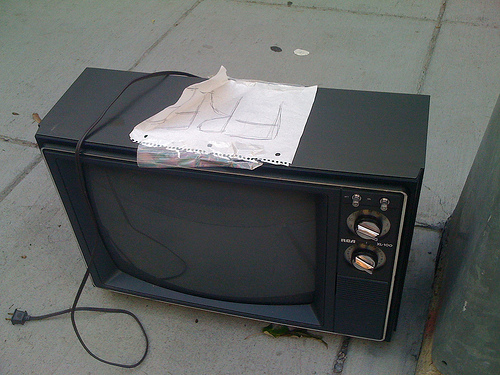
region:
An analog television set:
[40, 70, 408, 328]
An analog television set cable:
[5, 293, 156, 368]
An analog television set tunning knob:
[350, 241, 385, 274]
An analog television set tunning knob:
[348, 208, 387, 240]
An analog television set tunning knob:
[376, 196, 392, 213]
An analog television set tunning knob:
[347, 187, 362, 207]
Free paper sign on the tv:
[132, 74, 319, 167]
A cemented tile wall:
[161, 16, 445, 91]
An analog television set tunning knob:
[9, 167, 71, 279]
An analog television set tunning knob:
[1, 326, 84, 367]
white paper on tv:
[135, 74, 337, 186]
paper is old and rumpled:
[137, 66, 324, 184]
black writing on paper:
[136, 56, 266, 175]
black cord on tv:
[25, 54, 184, 374]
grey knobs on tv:
[326, 214, 379, 286]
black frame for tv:
[63, 63, 402, 355]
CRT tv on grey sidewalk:
[42, 55, 397, 352]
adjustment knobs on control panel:
[344, 191, 384, 291]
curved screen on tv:
[99, 163, 301, 330]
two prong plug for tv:
[12, 301, 38, 335]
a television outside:
[16, 58, 453, 359]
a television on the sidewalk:
[23, 54, 424, 372]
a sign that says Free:
[135, 73, 307, 174]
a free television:
[41, 63, 437, 348]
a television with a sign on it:
[21, 56, 446, 366]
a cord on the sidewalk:
[6, 298, 168, 365]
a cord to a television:
[4, 52, 155, 372]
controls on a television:
[336, 189, 395, 280]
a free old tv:
[9, 50, 436, 374]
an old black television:
[4, 53, 431, 370]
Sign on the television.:
[137, 63, 319, 171]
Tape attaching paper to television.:
[131, 134, 263, 179]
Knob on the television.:
[347, 203, 382, 285]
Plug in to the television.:
[2, 303, 43, 331]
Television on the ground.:
[27, 61, 435, 358]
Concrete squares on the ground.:
[2, 1, 495, 373]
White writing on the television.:
[337, 234, 358, 248]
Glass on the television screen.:
[64, 154, 330, 306]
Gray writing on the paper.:
[152, 83, 284, 142]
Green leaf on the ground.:
[239, 321, 330, 357]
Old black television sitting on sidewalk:
[36, 67, 433, 344]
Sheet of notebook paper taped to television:
[128, 63, 318, 171]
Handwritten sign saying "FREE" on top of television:
[129, 63, 319, 169]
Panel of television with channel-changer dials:
[320, 185, 409, 344]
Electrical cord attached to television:
[6, 70, 201, 369]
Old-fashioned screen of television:
[78, 160, 323, 307]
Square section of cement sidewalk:
[124, 1, 442, 93]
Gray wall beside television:
[413, 95, 498, 372]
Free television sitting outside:
[35, 65, 432, 342]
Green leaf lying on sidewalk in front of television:
[243, 323, 330, 348]